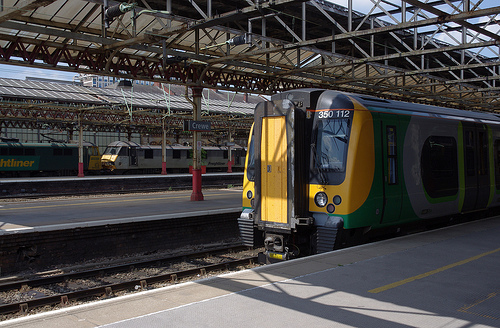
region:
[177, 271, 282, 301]
caution area on a platform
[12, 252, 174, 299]
tracks of the train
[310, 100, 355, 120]
Identification number on a train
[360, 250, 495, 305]
yellow lines on the platform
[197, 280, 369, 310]
shadows from girders above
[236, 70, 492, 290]
commuter train in the station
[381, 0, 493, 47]
sky seen through girders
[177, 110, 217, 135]
name of the station stop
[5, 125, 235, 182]
two trains on the track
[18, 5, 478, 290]
busy train station during the day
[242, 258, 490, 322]
paved walkway next to train with orange painted lines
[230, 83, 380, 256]
yellow and black front end of a train engine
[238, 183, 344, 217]
lights in the front of a train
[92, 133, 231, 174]
yellow and black train on the track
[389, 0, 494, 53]
blue sky with white clouds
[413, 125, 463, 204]
window in the side of a train engine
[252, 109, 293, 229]
yellow door at the end of a train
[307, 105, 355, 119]
white numbers under a red line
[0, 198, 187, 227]
paved platform between train tracks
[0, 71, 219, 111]
roof of train station building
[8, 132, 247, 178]
A set of train on the track.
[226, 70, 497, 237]
Train on the track.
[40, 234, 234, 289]
Gravel between the tracks.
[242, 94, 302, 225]
The yellow door on the train.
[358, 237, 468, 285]
Yellow lines on the walkway.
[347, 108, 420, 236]
The train is green by the window.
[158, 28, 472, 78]
Iron railing on the top of the station.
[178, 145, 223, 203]
Pole is red at the bottom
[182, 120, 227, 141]
A blue sign on the pole.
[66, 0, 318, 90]
The roof of the station.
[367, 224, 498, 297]
Yellow line on asphalt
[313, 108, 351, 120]
White numbers on front of train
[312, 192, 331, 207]
Round headlight on train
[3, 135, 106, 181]
Green and yellow train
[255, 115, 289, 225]
Yellow door on front of train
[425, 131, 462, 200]
Large window on side of train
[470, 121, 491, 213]
Passenger door on train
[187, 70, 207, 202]
Metal support pole near tracks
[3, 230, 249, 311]
Rusty train tracks near road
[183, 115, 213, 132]
Sign fastened to pole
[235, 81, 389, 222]
yellow front of train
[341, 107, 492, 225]
green side of train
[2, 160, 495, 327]
platforms of either side of train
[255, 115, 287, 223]
yellow door of train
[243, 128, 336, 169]
front windows of train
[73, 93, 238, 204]
steel poles with red bottoms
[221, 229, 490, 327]
shadow on train platform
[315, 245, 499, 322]
yellow lines painted o platform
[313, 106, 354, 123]
white numbers on front of train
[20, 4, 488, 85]
steel support beams above train